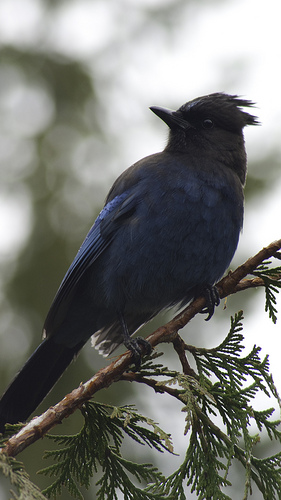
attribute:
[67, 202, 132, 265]
feathers — blue, black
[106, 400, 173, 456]
needles — browning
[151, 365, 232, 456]
needles — browning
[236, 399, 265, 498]
needles — browning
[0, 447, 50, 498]
needles — browning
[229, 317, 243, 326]
leaf — green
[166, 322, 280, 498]
leaves — green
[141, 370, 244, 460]
leaves — green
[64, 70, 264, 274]
bird — feathery, black, blue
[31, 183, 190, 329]
feathers — black, blue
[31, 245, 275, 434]
limb — black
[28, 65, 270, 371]
bird — black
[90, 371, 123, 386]
bark — brown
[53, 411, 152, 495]
leaves — green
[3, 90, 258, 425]
bird — blue, black, feathery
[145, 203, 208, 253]
feathers — blue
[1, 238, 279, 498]
tree — evergreen